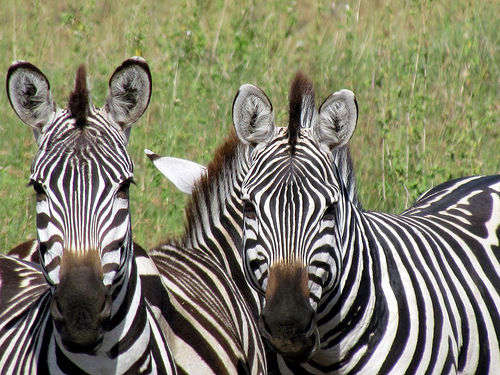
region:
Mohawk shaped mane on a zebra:
[280, 71, 322, 157]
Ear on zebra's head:
[229, 80, 270, 150]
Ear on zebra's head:
[319, 90, 359, 145]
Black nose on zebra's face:
[257, 293, 322, 335]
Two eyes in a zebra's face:
[32, 175, 131, 196]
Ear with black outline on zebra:
[4, 61, 63, 126]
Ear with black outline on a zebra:
[105, 52, 150, 124]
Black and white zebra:
[0, 56, 270, 373]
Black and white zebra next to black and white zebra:
[6, 55, 265, 373]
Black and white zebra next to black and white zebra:
[232, 71, 499, 373]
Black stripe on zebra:
[364, 211, 409, 373]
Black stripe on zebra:
[366, 212, 426, 374]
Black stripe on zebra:
[140, 270, 227, 373]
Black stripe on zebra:
[425, 211, 499, 289]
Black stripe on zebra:
[298, 213, 360, 328]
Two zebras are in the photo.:
[1, 51, 496, 372]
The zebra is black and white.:
[229, 69, 499, 373]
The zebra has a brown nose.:
[229, 82, 359, 362]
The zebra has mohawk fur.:
[282, 71, 371, 215]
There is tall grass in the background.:
[2, 2, 494, 245]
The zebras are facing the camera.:
[1, 57, 499, 364]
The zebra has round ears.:
[4, 52, 158, 132]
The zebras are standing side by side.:
[3, 57, 498, 374]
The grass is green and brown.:
[1, 2, 496, 233]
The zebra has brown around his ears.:
[1, 57, 166, 351]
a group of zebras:
[3, 54, 499, 374]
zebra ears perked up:
[4, 56, 156, 135]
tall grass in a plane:
[1, 3, 499, 199]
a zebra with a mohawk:
[234, 71, 496, 367]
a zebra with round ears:
[3, 56, 153, 374]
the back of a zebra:
[131, 125, 272, 374]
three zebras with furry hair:
[1, 54, 499, 374]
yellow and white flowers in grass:
[62, 13, 203, 59]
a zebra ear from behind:
[142, 144, 235, 204]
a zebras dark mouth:
[255, 258, 321, 364]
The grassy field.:
[14, 1, 498, 239]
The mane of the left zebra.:
[64, 58, 98, 120]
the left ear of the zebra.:
[1, 59, 65, 130]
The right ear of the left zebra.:
[108, 65, 165, 132]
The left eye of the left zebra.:
[28, 173, 71, 213]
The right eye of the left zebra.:
[109, 162, 152, 213]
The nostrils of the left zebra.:
[41, 285, 124, 322]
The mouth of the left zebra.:
[49, 332, 102, 357]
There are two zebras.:
[7, 45, 493, 372]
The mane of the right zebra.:
[281, 63, 316, 146]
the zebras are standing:
[0, 54, 499, 373]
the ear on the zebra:
[315, 87, 358, 151]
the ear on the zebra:
[233, 82, 275, 144]